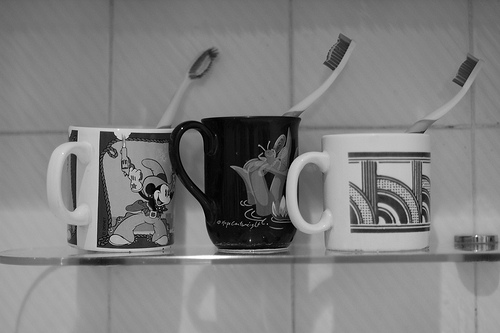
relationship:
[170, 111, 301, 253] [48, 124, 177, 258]
cup next to a cup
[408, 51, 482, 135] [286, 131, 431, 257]
toothbrush in a cups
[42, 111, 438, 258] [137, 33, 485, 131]
cups are holding toothbrushes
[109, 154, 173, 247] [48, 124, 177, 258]
mickey mouse on cup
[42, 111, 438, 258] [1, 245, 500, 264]
cups are on a shelf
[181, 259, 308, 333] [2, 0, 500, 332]
shadow on wall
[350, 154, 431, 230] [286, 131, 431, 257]
image on cups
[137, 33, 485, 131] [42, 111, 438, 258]
toothbrushes are in cups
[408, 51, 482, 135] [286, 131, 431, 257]
toothbrush in cups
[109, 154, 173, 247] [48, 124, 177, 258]
mickey mouse on a cup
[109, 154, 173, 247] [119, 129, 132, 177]
mickey mouse holding gun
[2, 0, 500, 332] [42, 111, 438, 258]
wall behind cups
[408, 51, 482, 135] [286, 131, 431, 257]
toothbrush inside of a cups